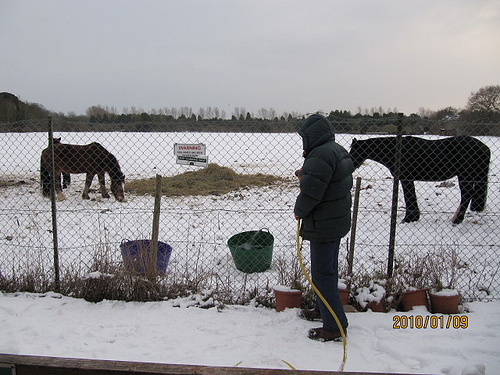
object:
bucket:
[227, 227, 274, 273]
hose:
[234, 217, 347, 372]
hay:
[124, 163, 300, 197]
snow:
[0, 131, 500, 375]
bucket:
[119, 239, 172, 277]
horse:
[349, 135, 491, 227]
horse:
[40, 142, 125, 202]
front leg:
[97, 171, 111, 198]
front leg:
[82, 172, 96, 200]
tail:
[40, 146, 51, 197]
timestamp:
[393, 315, 468, 329]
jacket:
[293, 113, 355, 243]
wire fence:
[0, 119, 500, 305]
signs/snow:
[174, 143, 209, 168]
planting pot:
[424, 246, 469, 315]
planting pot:
[393, 254, 430, 312]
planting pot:
[338, 278, 351, 305]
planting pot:
[273, 257, 309, 313]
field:
[0, 131, 500, 308]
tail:
[470, 138, 491, 212]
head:
[348, 137, 367, 168]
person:
[293, 114, 356, 342]